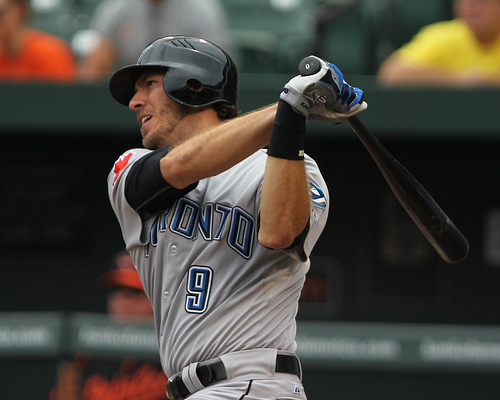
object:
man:
[105, 32, 469, 400]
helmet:
[106, 34, 239, 107]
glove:
[275, 53, 368, 126]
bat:
[297, 55, 470, 265]